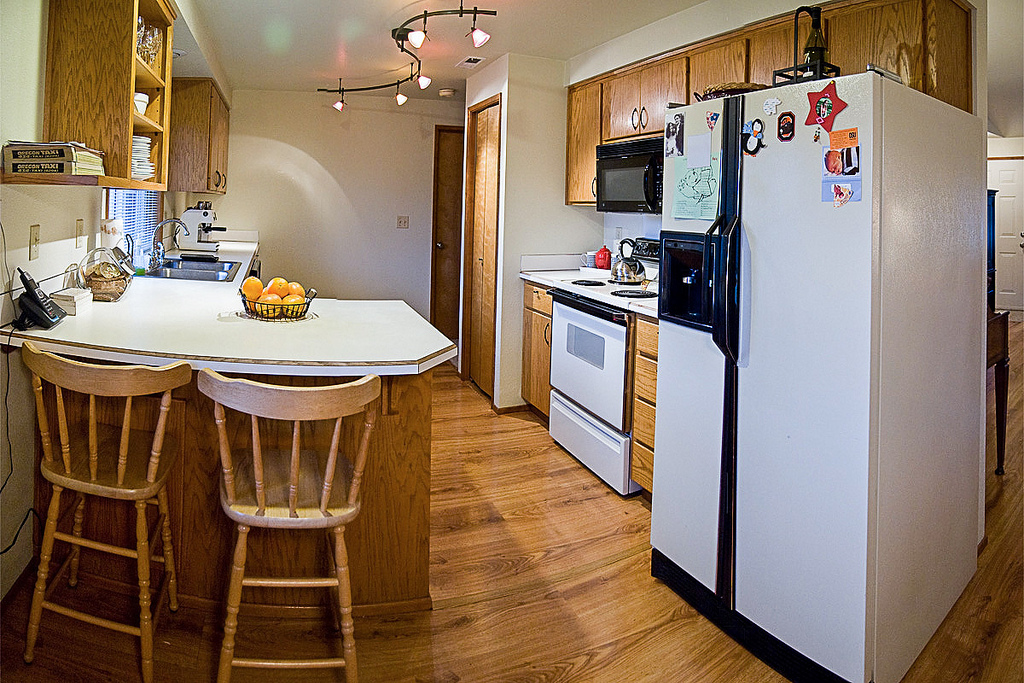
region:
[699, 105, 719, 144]
magnet on the fridge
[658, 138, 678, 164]
magnet on the fridge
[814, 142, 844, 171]
magnet on the fridge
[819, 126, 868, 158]
magnet on the fridge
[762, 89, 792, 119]
magnet on the fridge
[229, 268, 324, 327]
A basket of oranges.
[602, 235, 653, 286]
A teapot on the stove.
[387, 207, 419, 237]
A double lightswitch on the wall.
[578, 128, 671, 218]
A black microwave above the stove.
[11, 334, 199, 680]
A wood stool closest to the wall.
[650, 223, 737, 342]
A black dispensor in the door of the refrigerator.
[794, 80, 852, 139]
A red star on the refrigerator.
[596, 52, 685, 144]
Two cupboard doors above the microwave.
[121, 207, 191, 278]
A chrome kitchen faucet.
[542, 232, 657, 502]
A white kitchen stove and oven.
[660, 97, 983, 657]
a large white refrigerator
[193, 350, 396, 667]
a kitchen stool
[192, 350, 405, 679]
A kitchen stool pushed up to the counter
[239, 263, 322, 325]
A basket of oranges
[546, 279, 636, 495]
A white oven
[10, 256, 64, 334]
a Telephone on the kitchen counter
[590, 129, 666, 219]
a Black microwave oven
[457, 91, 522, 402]
the door to the pantry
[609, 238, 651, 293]
A silver kettle on the stove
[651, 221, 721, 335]
an icemaker on the refrigerator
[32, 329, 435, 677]
brown chairs at counter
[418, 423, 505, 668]
floor is light brown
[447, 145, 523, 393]
brown door in kitchen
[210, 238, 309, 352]
oranges in black bowl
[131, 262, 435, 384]
white counter with bowl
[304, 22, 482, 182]
s-shaped light over kitchen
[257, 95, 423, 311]
white wall in kitchen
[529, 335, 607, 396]
oven door is white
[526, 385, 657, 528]
white storage drawer under oven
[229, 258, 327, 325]
A bowl of fruit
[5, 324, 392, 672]
Two tall wooden chairs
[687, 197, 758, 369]
Black handles of a fridge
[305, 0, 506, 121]
Lights on the ceiling are turned on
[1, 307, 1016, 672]
A brown wooden floor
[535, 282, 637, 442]
A white oven door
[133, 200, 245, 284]
A faucet over a double sink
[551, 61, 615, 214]
A brown wooden cabinet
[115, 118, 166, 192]
A stack of white plates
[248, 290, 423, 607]
a wooden chair under the table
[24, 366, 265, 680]
a wooden chair under the counter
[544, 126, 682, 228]
a black kitchen microwave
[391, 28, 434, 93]
lights on the ceiling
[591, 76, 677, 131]
wooden cabinets above the micro wave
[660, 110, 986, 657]
a white refrigerator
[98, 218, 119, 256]
a roll of paper towels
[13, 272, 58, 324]
a black telephone on the counter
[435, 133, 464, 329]
a wooden door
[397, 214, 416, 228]
a light switch on the wall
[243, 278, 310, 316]
oranges in a bowl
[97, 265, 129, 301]
a basket on the counter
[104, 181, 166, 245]
a window on the wall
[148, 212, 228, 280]
the sink on the counter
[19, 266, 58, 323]
a black telephone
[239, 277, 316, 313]
a bowl of fruit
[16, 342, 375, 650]
two wooden bar stools